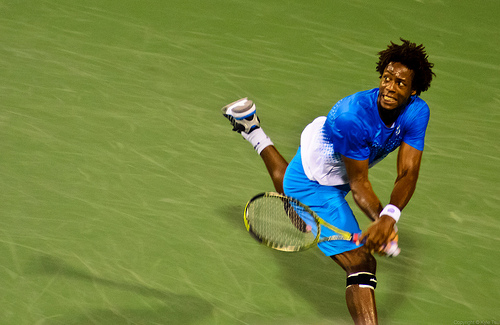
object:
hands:
[359, 215, 397, 253]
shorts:
[282, 147, 364, 258]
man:
[220, 38, 436, 325]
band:
[346, 272, 378, 291]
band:
[379, 204, 401, 223]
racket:
[243, 191, 400, 258]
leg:
[330, 248, 379, 325]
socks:
[239, 126, 274, 155]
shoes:
[220, 97, 260, 134]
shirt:
[300, 87, 430, 187]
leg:
[238, 129, 314, 232]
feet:
[221, 97, 260, 134]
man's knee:
[345, 257, 377, 273]